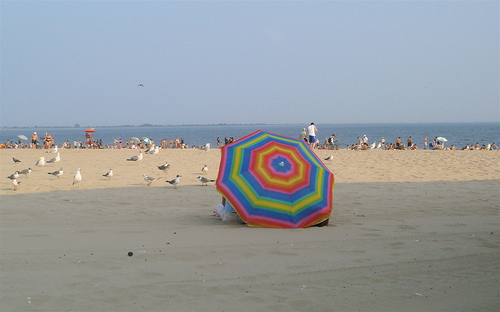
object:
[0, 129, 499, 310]
beach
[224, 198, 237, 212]
shirt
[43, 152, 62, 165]
birds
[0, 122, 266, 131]
island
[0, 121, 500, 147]
water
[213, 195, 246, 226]
person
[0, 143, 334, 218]
seagulls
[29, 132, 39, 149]
man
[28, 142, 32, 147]
trunks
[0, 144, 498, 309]
sand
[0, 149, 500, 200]
sun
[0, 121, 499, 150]
people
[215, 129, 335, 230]
colored umbrellas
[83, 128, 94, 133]
colored umbrellas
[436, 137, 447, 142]
colored umbrellas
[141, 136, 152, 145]
colored umbrellas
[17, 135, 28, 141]
colored umbrellas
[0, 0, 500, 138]
sky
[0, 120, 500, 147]
ocean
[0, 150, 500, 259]
ground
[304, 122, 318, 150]
man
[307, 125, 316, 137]
shirt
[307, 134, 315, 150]
trunks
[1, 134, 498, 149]
seashore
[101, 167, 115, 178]
bird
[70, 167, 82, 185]
bird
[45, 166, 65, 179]
bird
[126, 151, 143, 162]
bird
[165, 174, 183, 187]
bird